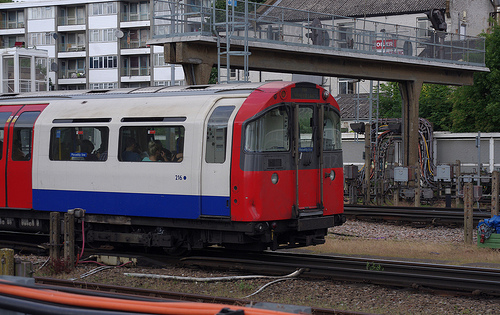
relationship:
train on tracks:
[1, 80, 345, 259] [0, 228, 499, 295]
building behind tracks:
[0, 1, 410, 126] [20, 237, 484, 313]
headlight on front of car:
[270, 172, 280, 184] [0, 80, 346, 254]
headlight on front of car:
[330, 170, 335, 180] [0, 80, 346, 254]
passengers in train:
[119, 123, 183, 161] [1, 80, 345, 259]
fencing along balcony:
[140, 3, 479, 63] [302, 18, 441, 49]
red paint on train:
[233, 78, 346, 227] [1, 80, 345, 259]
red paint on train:
[0, 103, 47, 210] [1, 80, 345, 259]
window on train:
[118, 123, 185, 164] [1, 80, 345, 259]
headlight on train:
[330, 170, 335, 180] [1, 80, 345, 259]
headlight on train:
[270, 172, 280, 184] [1, 80, 345, 259]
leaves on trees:
[442, 97, 477, 116] [371, 23, 481, 123]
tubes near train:
[2, 283, 302, 313] [1, 80, 345, 259]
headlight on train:
[270, 172, 280, 184] [0, 63, 362, 262]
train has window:
[1, 80, 345, 259] [117, 126, 182, 160]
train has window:
[1, 80, 345, 259] [46, 126, 109, 160]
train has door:
[1, 80, 345, 259] [0, 100, 51, 212]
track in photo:
[373, 258, 450, 278] [0, 3, 494, 313]